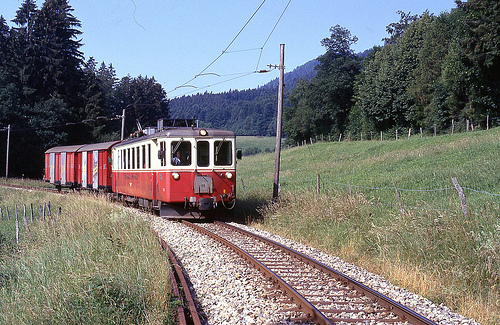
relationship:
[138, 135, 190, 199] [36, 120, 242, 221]
door on train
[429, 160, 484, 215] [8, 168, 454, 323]
ground by train tracks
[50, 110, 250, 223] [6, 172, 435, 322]
train on tracks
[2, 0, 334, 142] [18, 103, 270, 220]
wires above train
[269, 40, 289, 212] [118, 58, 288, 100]
pole holding wires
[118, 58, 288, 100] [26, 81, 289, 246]
wires above train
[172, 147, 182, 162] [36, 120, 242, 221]
conductor of train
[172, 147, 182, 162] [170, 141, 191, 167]
conductor in window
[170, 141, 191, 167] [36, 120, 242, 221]
window of train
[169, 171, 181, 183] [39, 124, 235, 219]
headlight on train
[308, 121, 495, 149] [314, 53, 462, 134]
fence in front of trees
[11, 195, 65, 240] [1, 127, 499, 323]
stakes in ground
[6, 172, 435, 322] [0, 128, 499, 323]
tracks on floor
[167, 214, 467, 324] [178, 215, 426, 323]
path on train tracks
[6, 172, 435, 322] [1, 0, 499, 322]
tracks in forrest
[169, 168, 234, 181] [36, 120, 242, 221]
headlight on train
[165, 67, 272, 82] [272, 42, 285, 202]
wires on pole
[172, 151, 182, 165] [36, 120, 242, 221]
conductor inside train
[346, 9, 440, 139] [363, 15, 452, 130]
branches on tree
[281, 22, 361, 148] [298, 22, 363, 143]
branches on tree